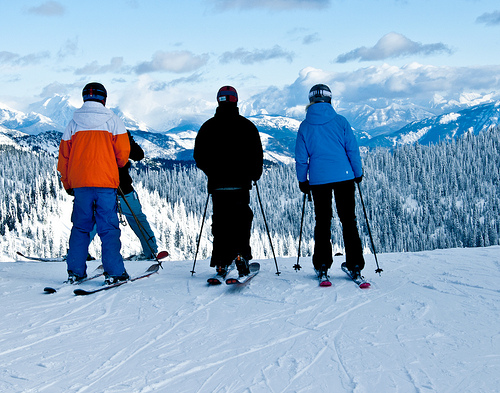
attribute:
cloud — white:
[335, 30, 455, 66]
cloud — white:
[238, 65, 499, 110]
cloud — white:
[74, 45, 296, 76]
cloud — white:
[104, 73, 216, 129]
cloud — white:
[41, 76, 83, 95]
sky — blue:
[0, 0, 499, 102]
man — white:
[40, 71, 150, 296]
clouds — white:
[344, 32, 495, 95]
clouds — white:
[132, 42, 307, 78]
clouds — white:
[244, 79, 297, 111]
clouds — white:
[2, 2, 135, 80]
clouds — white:
[210, 0, 348, 14]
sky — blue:
[2, 2, 495, 92]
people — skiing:
[59, 82, 344, 176]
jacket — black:
[189, 102, 266, 194]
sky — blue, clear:
[186, 13, 376, 62]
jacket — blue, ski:
[295, 104, 364, 186]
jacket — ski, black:
[193, 104, 263, 191]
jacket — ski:
[55, 101, 131, 187]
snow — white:
[0, 245, 498, 392]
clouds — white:
[336, 30, 455, 59]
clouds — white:
[291, 65, 413, 85]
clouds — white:
[229, 48, 290, 62]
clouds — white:
[143, 50, 204, 75]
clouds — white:
[1, 50, 50, 69]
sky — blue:
[1, 0, 498, 130]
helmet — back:
[82, 81, 108, 106]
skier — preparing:
[291, 80, 368, 282]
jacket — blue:
[289, 102, 373, 194]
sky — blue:
[291, 13, 453, 77]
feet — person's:
[57, 264, 128, 286]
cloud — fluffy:
[332, 31, 454, 59]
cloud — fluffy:
[341, 62, 453, 94]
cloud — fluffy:
[129, 48, 213, 68]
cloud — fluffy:
[25, 2, 67, 17]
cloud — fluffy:
[203, 3, 333, 11]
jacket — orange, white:
[59, 100, 132, 190]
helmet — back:
[210, 83, 240, 108]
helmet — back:
[302, 80, 337, 107]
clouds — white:
[72, 45, 209, 75]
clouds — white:
[383, 17, 471, 91]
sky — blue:
[45, 11, 291, 81]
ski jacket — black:
[189, 118, 276, 205]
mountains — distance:
[353, 85, 494, 149]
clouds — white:
[0, 3, 480, 130]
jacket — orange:
[61, 100, 128, 183]